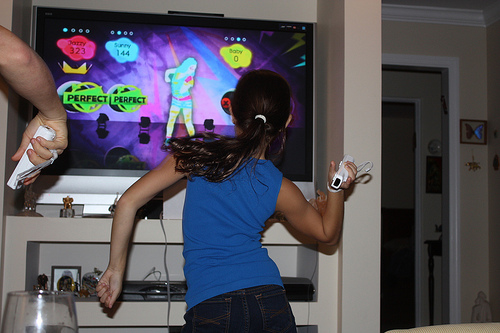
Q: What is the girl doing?
A: Playing a video game.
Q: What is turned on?
A: TV screen.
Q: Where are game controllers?
A: In people's hands.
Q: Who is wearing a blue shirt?
A: The girl.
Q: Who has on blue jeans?
A: A girl.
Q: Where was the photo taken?
A: In a house.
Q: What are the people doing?
A: Playing.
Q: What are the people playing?
A: Video games.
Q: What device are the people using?
A: Wii.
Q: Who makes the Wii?
A: Nintendo.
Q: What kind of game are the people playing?
A: Dancing.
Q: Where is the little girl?
A: In front of a television.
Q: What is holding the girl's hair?
A: Hairband.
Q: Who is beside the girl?
A: A man.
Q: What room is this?
A: Entertainment room.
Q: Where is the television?
A: On the entertainment center.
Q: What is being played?
A: Video games.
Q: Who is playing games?
A: The girl.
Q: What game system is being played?
A: Wii.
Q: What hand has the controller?
A: Right.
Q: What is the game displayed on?
A: T.v.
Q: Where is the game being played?
A: Living room.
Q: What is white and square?
A: Door frame.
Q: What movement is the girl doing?
A: Dance.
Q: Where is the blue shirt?
A: On the girl.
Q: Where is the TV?
A: Wall.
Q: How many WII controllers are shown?
A: Two.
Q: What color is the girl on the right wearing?
A: Blue.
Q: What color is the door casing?
A: White.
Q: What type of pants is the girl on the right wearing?
A: Jeans.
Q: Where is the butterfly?
A: Beside door casing.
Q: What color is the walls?
A: Peach.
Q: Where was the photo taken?
A: In a room.